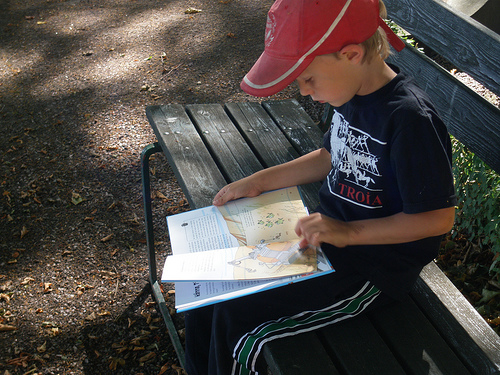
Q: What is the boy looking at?
A: Book.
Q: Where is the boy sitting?
A: On a wooden bench.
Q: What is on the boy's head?
A: Red and white baseball cap.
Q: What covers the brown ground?
A: Scattered leaves.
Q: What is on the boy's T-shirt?
A: White design and red letters.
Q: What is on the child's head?
A: Cap.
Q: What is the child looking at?
A: Book.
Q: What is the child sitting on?
A: Bench.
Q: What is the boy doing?
A: Reading.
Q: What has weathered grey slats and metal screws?
A: A bench.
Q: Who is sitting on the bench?
A: A boy, reading a book.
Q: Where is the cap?
A: On the head of the boy, who is reading.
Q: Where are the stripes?
A: On the hat, the shirt, and the pants of the reading boy.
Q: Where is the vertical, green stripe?
A: On the boy's pants.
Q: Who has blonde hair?
A: A little boy, reading a book, on a bench.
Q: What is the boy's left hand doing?
A: Turning the page of a book.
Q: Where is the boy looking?
A: Down, at a book.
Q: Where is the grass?
A: Behind the bench.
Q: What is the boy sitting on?
A: Bench.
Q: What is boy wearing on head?
A: Hat.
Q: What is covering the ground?
A: Leaves.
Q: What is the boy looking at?
A: Book.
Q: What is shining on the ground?
A: Sunlight.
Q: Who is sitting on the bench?
A: Small boy.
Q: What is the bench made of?
A: Wood.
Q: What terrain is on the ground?
A: Sand.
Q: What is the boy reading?
A: Book.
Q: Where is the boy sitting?
A: Park.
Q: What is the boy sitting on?
A: A bench.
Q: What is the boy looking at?
A: A book.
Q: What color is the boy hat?
A: Red.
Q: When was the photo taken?
A: Daytime.